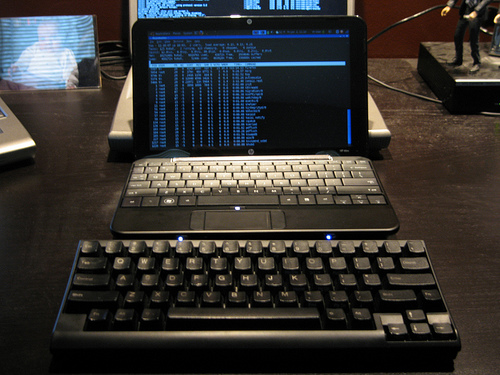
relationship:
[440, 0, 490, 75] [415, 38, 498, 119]
figure on pedestal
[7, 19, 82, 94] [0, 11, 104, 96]
baby on photo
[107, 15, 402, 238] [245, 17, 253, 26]
laptop has camera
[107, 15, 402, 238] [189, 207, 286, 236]
laptop has mouse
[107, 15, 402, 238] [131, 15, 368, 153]
laptop has display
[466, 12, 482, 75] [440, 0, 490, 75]
leg of figure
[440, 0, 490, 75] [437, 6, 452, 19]
figure has hand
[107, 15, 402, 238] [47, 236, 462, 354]
laptop has keyboard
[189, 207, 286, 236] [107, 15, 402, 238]
mouse on laptop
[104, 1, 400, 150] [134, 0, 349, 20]
laptop has screen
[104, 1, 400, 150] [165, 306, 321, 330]
laptop has spacebar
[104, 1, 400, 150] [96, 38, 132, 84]
laptop has cables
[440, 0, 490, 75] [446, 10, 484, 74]
figure has legs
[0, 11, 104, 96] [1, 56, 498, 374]
photo on table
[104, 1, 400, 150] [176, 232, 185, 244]
laptop has lights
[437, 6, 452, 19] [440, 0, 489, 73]
hand of figure